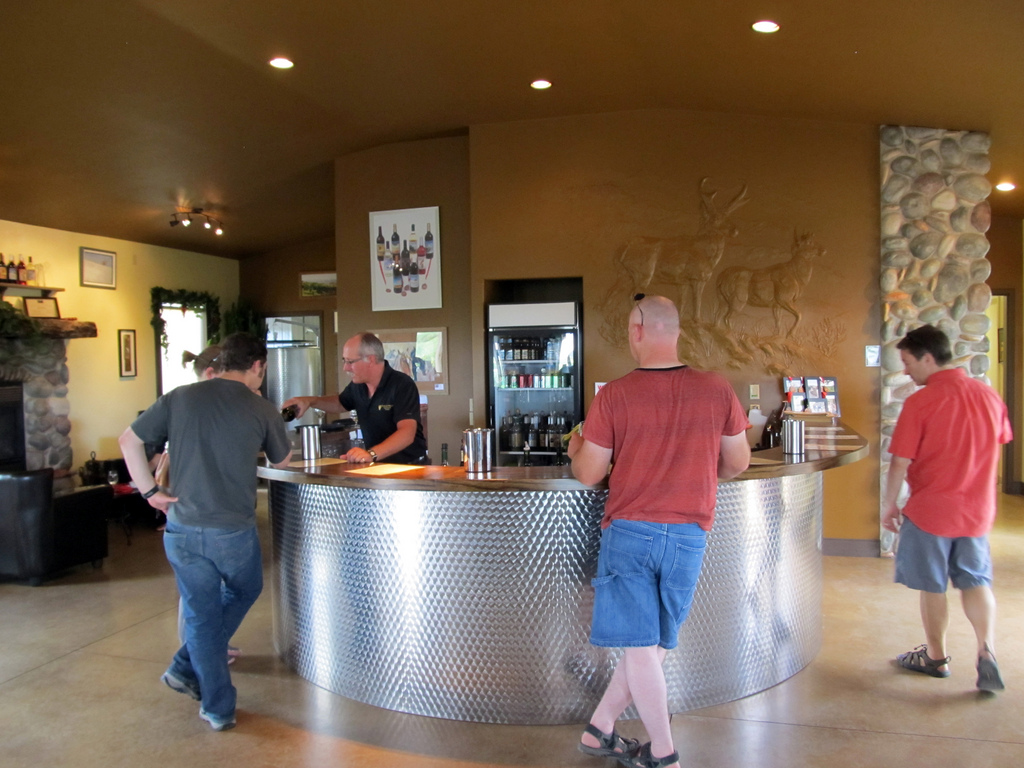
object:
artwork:
[368, 206, 446, 312]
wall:
[875, 123, 999, 585]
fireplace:
[0, 302, 102, 497]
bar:
[256, 382, 873, 731]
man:
[564, 293, 761, 767]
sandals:
[580, 721, 644, 757]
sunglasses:
[632, 291, 664, 325]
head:
[626, 292, 682, 372]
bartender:
[282, 330, 435, 464]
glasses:
[341, 357, 375, 365]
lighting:
[268, 46, 298, 70]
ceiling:
[0, 6, 1024, 237]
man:
[116, 331, 295, 736]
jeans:
[160, 508, 267, 727]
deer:
[592, 177, 831, 378]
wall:
[450, 109, 886, 523]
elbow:
[570, 459, 609, 487]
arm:
[566, 386, 617, 488]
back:
[609, 369, 720, 519]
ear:
[633, 323, 644, 343]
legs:
[166, 552, 239, 713]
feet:
[610, 742, 685, 767]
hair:
[219, 330, 268, 371]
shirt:
[130, 378, 293, 534]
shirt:
[580, 364, 757, 531]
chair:
[0, 464, 116, 588]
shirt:
[334, 359, 430, 465]